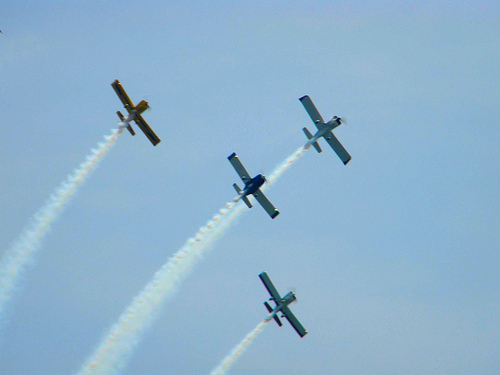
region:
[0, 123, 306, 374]
smoke in air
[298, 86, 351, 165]
the leading aircraft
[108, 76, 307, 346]
third in line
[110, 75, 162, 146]
red tint chopper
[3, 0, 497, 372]
a blue sky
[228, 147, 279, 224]
second in line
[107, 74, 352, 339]
four choppers in the air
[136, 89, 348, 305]
propellars on choppers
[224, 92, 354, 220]
two choppers lined up behind each other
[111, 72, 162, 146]
left side chopper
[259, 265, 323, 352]
this is a plane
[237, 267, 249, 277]
the plane is small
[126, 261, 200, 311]
this is a cloud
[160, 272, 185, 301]
the cloud is long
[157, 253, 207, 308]
the cloud is white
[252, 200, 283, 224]
this is a wing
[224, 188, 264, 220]
this is a tail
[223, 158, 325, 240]
the planes are tiny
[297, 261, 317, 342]
the planes are long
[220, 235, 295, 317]
the wing is long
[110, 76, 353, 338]
planes flying in squadron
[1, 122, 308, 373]
white jetstream coming from tails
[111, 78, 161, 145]
dark colored plane in air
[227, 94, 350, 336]
blue and white air planes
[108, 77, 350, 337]
airplanes have propeller engines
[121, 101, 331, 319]
the wheels on airplanes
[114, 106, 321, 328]
tails on airplanes have fins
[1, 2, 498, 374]
sky is clear and blue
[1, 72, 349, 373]
airplanes are leaving jet streams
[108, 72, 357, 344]
planes flying in formation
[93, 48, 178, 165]
a plane in the air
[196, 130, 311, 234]
a plane flying in the air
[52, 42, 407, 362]
a group of planes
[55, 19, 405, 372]
a group of planes flying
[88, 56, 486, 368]
a group of planes flying in air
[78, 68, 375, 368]
a group of planes flying near sky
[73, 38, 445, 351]
a group of planes flying near clouds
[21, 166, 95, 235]
a white smoke from plane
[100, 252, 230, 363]
white lines in the sky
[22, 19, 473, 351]
a clear view of sky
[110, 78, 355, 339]
Four planes in the sky.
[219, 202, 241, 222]
Smoke from the plane.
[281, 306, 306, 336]
The wing of the plane.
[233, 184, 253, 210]
The tail of the plane.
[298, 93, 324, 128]
The wing of the plane.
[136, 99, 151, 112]
The nose of the plane.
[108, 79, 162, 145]
A yellow plane in the air.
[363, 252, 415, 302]
Part of the sky.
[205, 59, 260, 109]
Part of the blue sky.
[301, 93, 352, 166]
A green plane in the air.